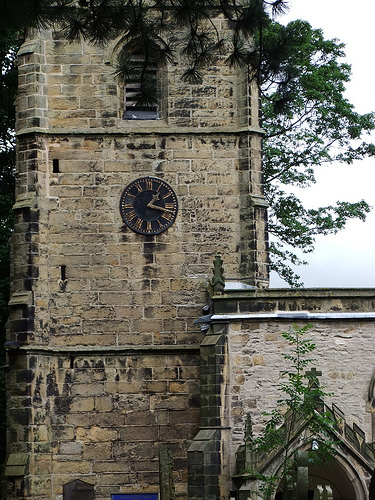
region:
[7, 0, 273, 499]
An old clock tower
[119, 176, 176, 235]
A clock on the clock tower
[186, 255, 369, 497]
A large stone building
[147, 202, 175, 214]
the minute hand of a clock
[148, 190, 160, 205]
the hour hand of a clock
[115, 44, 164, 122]
A window on the tower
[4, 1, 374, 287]
Some tree branches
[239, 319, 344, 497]
A small thin plant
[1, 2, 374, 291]
A cloudy sky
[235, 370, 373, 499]
A stone archway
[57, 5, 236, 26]
Tree leaves covering a tower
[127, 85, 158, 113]
The tower window and a branch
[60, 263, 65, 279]
A hole in the tower wall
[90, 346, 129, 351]
A ledge on the tower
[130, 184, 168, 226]
A clock on the tower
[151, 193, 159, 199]
The clock's hour hand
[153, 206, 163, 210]
The clock's minute hand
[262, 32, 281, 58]
Branches sticking out behind the tower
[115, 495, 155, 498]
A blue wooden door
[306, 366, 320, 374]
A cross sticking out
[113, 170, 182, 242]
a clock in a tower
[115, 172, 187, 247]
clock is brown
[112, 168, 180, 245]
clock has roman numerals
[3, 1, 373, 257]
a tree behind a tower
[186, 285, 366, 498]
a plant in front a building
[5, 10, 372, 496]
an old tower next a building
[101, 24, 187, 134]
a small window over a clock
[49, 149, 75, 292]
two openings on left side of clock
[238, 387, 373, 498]
door of a building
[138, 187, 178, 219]
hands of clock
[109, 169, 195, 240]
clock on the tower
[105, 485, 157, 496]
blue on the building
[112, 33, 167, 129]
window on the building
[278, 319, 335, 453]
green tree in front of the building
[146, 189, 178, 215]
gold hands on the clock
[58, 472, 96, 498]
brown door on the tower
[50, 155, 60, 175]
hole in the wall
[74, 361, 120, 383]
black mark on the stone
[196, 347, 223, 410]
black and gray bricks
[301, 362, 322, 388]
cross on the wall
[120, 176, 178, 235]
black clock on church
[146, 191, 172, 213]
metal hands on the clock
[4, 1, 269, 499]
tall stone tower on church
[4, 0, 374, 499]
old worn stone church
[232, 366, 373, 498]
decorative door frame on church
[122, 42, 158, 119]
vents over clock on tower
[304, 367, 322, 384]
small cross over doorway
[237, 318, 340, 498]
short tree in front church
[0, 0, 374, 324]
trees behind church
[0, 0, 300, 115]
pine tree branch in front church